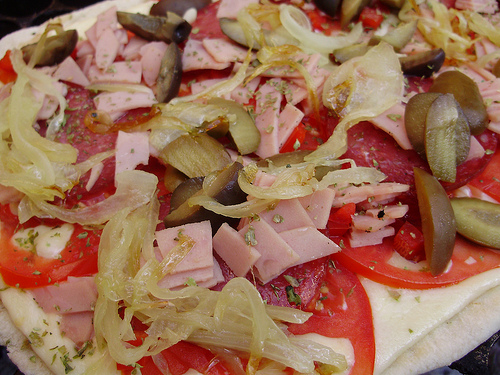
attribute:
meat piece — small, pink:
[259, 201, 314, 234]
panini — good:
[2, 0, 497, 373]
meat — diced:
[230, 171, 377, 292]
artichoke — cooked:
[402, 154, 462, 285]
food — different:
[1, 1, 498, 373]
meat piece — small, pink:
[97, 120, 167, 184]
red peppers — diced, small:
[361, 201, 433, 264]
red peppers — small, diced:
[225, 70, 445, 197]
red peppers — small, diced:
[8, 13, 194, 181]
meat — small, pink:
[253, 75, 283, 160]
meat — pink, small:
[209, 220, 261, 282]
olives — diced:
[414, 174, 456, 271]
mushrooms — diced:
[114, 9, 186, 82]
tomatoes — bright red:
[305, 78, 498, 294]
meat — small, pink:
[2, 0, 499, 375]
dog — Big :
[217, 77, 369, 166]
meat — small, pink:
[152, 222, 213, 271]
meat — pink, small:
[212, 183, 374, 309]